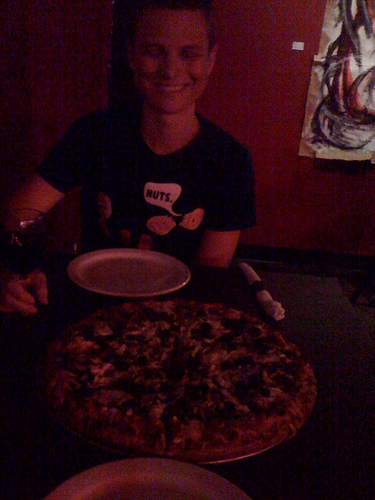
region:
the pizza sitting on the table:
[30, 297, 316, 468]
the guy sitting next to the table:
[10, 6, 238, 292]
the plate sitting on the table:
[64, 246, 192, 294]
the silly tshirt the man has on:
[43, 110, 255, 257]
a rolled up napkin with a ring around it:
[234, 253, 288, 322]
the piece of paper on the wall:
[295, 2, 373, 168]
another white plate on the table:
[44, 455, 247, 498]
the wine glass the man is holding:
[1, 206, 51, 285]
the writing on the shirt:
[142, 180, 174, 206]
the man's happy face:
[133, 26, 208, 109]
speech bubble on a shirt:
[137, 181, 185, 220]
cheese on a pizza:
[126, 333, 216, 416]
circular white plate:
[59, 239, 200, 302]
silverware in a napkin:
[235, 257, 291, 330]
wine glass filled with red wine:
[7, 210, 45, 308]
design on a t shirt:
[126, 173, 204, 236]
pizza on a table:
[33, 282, 323, 471]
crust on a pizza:
[290, 400, 310, 426]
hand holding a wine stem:
[7, 267, 50, 320]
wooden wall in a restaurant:
[258, 175, 336, 232]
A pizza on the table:
[39, 301, 316, 456]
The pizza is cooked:
[44, 301, 315, 456]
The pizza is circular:
[45, 299, 317, 458]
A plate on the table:
[68, 248, 189, 294]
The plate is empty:
[66, 247, 189, 295]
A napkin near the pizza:
[240, 262, 283, 318]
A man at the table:
[0, 7, 255, 313]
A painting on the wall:
[297, 2, 374, 160]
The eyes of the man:
[144, 47, 199, 58]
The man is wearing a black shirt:
[42, 108, 253, 259]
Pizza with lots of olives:
[30, 289, 314, 466]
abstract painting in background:
[294, 0, 374, 177]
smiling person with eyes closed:
[117, 4, 226, 111]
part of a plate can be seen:
[34, 451, 259, 499]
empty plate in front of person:
[63, 239, 201, 302]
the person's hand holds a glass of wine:
[0, 196, 58, 319]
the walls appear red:
[237, 21, 276, 108]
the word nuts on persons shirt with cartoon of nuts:
[132, 163, 218, 247]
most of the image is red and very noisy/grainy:
[16, 11, 294, 334]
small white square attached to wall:
[290, 35, 310, 59]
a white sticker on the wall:
[289, 36, 309, 52]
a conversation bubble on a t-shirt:
[146, 176, 186, 217]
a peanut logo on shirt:
[86, 219, 206, 243]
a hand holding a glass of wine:
[4, 273, 47, 314]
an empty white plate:
[53, 460, 241, 498]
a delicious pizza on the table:
[52, 299, 306, 454]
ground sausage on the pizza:
[198, 320, 215, 335]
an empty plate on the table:
[60, 240, 188, 302]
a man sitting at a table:
[33, 26, 240, 247]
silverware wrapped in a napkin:
[243, 262, 279, 313]